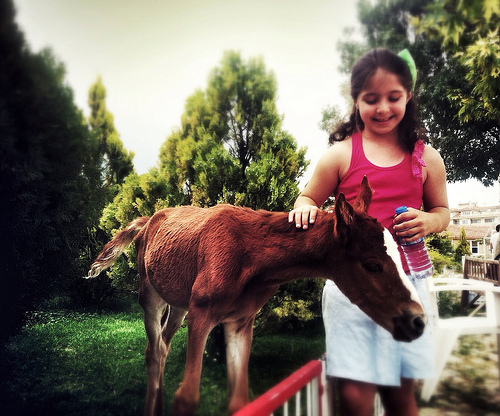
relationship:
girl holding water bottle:
[287, 43, 456, 416] [389, 200, 442, 288]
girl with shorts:
[287, 43, 456, 416] [342, 220, 492, 377]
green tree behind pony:
[97, 45, 312, 235] [77, 171, 426, 413]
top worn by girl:
[339, 141, 429, 268] [287, 43, 456, 416]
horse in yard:
[80, 172, 426, 414] [2, 298, 360, 414]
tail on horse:
[80, 214, 150, 280] [80, 173, 428, 414]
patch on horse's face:
[380, 224, 423, 300] [332, 199, 422, 336]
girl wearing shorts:
[287, 43, 456, 416] [321, 272, 441, 385]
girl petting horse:
[318, 43, 455, 356] [119, 172, 436, 398]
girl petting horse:
[287, 43, 456, 416] [80, 173, 428, 414]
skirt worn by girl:
[319, 267, 438, 382] [287, 43, 456, 416]